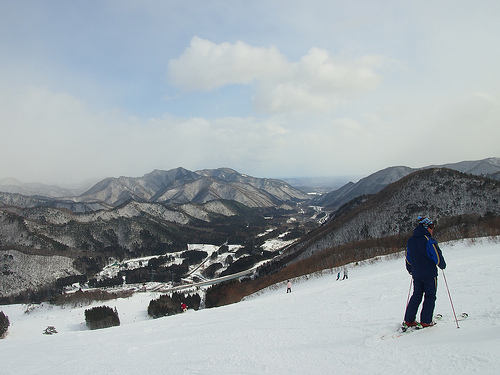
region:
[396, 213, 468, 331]
a skier on the ski slope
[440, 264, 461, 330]
a red ski pole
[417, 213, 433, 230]
a blue knit cap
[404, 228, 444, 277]
a black and blue ski jacket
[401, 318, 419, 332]
a red ski boot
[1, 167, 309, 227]
mountains in the distance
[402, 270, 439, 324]
blue and yellow ski pants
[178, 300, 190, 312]
a skier wearing a red ski jacket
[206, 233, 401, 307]
trees bordering the ski slope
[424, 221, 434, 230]
the skier ahs black ski goggles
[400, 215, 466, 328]
A person on skis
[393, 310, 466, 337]
Skis in the snow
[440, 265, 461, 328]
A ski pole on the snow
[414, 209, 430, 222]
The person is wearing a hat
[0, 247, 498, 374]
Snow on the hill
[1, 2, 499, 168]
The sky above the snow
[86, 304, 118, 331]
Trees on the white snow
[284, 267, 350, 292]
People on the hill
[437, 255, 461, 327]
A ski pole in the person's right hand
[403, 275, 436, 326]
The person is wearing pants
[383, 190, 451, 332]
skier in white snow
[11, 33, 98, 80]
white clouds in blue sky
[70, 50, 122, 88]
white clouds in blue sky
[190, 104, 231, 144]
white clouds in blue sky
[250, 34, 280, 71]
white clouds in blue sky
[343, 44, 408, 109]
white clouds in blue sky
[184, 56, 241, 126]
white clouds in blue sky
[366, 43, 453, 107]
white clouds in blue sky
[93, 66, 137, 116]
white clouds in blue sky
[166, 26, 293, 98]
white cloud in the sky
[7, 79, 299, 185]
white cloud in the sky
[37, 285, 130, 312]
cluster of brown trees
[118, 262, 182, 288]
cluster of brown trees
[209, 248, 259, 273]
cluster of brown trees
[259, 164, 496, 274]
brown and grey hill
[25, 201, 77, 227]
brown and grey hill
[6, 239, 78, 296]
brown and grey hill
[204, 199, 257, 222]
brown and grey hill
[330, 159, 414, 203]
brown and grey hill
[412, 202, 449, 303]
Man with blue and black cut in snow.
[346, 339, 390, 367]
Man with blue and black cut in snow.